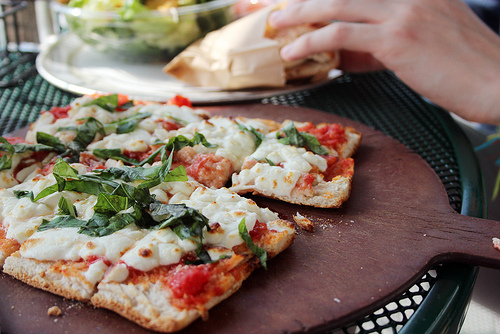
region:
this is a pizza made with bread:
[0, 88, 396, 311]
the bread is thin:
[7, 75, 385, 327]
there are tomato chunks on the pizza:
[0, 84, 364, 312]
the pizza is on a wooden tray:
[3, 108, 451, 333]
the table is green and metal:
[2, 39, 494, 331]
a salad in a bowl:
[50, 3, 245, 70]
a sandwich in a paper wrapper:
[173, 0, 366, 96]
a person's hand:
[258, 1, 495, 136]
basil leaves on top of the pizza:
[22, 118, 239, 250]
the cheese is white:
[0, 99, 311, 272]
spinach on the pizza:
[16, 115, 227, 265]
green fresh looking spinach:
[56, 143, 178, 233]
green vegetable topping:
[56, 152, 227, 265]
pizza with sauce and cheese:
[63, 223, 265, 317]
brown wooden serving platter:
[296, 196, 488, 286]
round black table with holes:
[373, 285, 476, 323]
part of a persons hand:
[265, 9, 490, 102]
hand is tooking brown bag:
[163, 18, 348, 102]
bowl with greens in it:
[51, 5, 236, 61]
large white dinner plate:
[28, 30, 203, 105]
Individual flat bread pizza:
[1, 84, 363, 329]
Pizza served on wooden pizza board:
[3, 91, 498, 331]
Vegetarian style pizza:
[2, 89, 369, 331]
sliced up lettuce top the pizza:
[0, 91, 360, 278]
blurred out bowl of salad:
[43, 1, 263, 74]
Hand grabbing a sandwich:
[250, 0, 497, 135]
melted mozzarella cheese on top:
[5, 93, 333, 294]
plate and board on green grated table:
[2, 29, 486, 331]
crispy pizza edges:
[327, 121, 369, 220]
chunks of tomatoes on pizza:
[155, 260, 220, 302]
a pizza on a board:
[2, 88, 387, 327]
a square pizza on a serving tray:
[7, 91, 363, 311]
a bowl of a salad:
[45, 0, 232, 55]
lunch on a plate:
[45, 0, 342, 87]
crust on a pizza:
[8, 249, 184, 317]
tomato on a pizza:
[137, 268, 218, 290]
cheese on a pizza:
[44, 228, 151, 260]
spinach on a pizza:
[68, 167, 184, 231]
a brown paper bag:
[178, 13, 286, 93]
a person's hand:
[263, 3, 499, 107]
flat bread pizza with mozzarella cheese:
[0, 80, 422, 324]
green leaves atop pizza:
[40, 158, 211, 234]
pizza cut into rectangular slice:
[233, 103, 358, 205]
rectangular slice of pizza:
[95, 183, 298, 323]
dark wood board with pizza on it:
[8, 76, 495, 331]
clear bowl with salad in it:
[47, 6, 237, 57]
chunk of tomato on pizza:
[165, 265, 221, 300]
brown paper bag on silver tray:
[167, 19, 353, 94]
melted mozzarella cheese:
[30, 220, 190, 270]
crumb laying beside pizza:
[39, 297, 79, 319]